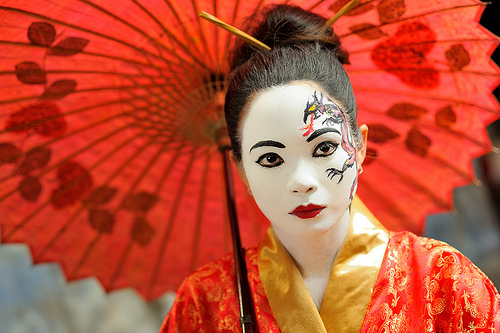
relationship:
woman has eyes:
[159, 3, 499, 331] [248, 128, 346, 170]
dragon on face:
[302, 96, 366, 177] [241, 91, 357, 233]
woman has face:
[159, 3, 499, 331] [241, 91, 357, 233]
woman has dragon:
[159, 3, 499, 331] [302, 96, 366, 177]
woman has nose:
[159, 3, 499, 331] [284, 167, 323, 193]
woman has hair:
[159, 3, 499, 331] [258, 56, 339, 78]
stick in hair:
[195, 10, 274, 51] [258, 56, 339, 78]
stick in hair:
[327, 2, 360, 32] [258, 56, 339, 78]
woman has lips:
[159, 3, 499, 331] [283, 199, 331, 221]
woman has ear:
[159, 3, 499, 331] [354, 123, 375, 172]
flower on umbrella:
[7, 100, 75, 140] [7, 4, 222, 255]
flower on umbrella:
[54, 159, 87, 214] [7, 4, 222, 255]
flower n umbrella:
[373, 22, 443, 95] [374, 6, 497, 206]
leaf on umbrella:
[17, 19, 55, 51] [7, 4, 222, 255]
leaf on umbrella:
[13, 60, 48, 87] [7, 4, 222, 255]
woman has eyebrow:
[159, 3, 499, 331] [304, 127, 345, 142]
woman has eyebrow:
[159, 3, 499, 331] [248, 137, 286, 152]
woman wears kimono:
[159, 3, 499, 331] [159, 236, 498, 331]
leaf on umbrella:
[129, 218, 155, 247] [7, 4, 222, 255]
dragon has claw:
[302, 96, 366, 177] [323, 165, 347, 187]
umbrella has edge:
[374, 6, 497, 206] [440, 136, 495, 230]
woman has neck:
[159, 3, 499, 331] [275, 233, 348, 282]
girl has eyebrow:
[153, 5, 498, 331] [248, 138, 286, 153]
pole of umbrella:
[221, 159, 250, 321] [2, 5, 484, 296]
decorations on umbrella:
[5, 18, 165, 247] [2, 5, 484, 296]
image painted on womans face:
[301, 88, 361, 217] [234, 77, 357, 239]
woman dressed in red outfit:
[159, 3, 499, 331] [159, 228, 497, 330]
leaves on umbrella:
[42, 153, 167, 249] [0, 0, 499, 330]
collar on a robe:
[264, 245, 376, 330] [158, 195, 498, 331]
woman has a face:
[159, 3, 499, 331] [234, 77, 357, 239]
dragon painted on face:
[303, 91, 360, 199] [234, 77, 357, 239]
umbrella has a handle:
[0, 0, 499, 330] [212, 144, 259, 330]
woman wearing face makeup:
[159, 3, 499, 331] [239, 82, 359, 311]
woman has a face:
[188, 3, 438, 285] [238, 71, 390, 258]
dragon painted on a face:
[303, 91, 360, 199] [238, 71, 390, 258]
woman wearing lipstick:
[159, 3, 499, 331] [286, 201, 328, 220]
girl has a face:
[153, 5, 498, 331] [234, 77, 357, 239]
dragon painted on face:
[287, 89, 379, 211] [234, 77, 357, 239]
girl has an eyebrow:
[153, 5, 498, 331] [241, 140, 322, 154]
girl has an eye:
[153, 5, 498, 331] [247, 143, 307, 178]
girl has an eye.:
[153, 5, 498, 331] [309, 137, 340, 156]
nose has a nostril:
[283, 152, 318, 199] [304, 182, 313, 192]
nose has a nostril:
[283, 152, 318, 199] [292, 187, 298, 196]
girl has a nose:
[153, 5, 498, 331] [283, 152, 318, 199]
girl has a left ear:
[153, 5, 498, 331] [229, 155, 249, 189]